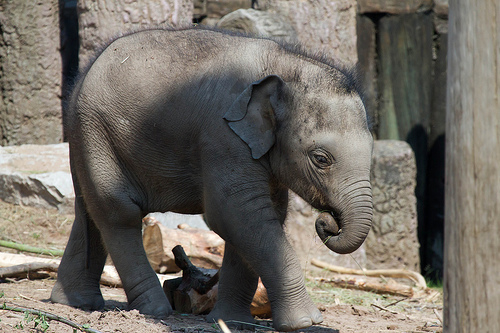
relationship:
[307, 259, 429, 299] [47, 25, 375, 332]
stick near elephant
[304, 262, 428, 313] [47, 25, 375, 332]
stick near elephant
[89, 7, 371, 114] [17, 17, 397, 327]
hair on elephant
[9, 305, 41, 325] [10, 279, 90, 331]
leaf on branch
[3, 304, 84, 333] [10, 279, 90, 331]
leaf on branch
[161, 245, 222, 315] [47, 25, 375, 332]
branches on side of elephant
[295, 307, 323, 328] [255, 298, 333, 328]
toe on foot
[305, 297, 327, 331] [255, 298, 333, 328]
toe on foot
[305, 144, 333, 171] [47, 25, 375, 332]
eye of elephant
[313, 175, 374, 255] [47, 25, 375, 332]
trunk of elephant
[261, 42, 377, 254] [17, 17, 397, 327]
head of elephant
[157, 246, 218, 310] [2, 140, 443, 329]
wood on ground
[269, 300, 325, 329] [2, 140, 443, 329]
foot on ground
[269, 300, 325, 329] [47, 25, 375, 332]
foot of elephant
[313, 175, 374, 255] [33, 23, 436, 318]
trunk of elephant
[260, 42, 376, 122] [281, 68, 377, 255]
fur growing on head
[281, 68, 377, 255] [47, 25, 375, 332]
head of elephant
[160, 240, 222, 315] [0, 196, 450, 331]
branches on ground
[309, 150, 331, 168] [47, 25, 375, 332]
eye of elephant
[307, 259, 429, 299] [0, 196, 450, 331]
stick laying on ground